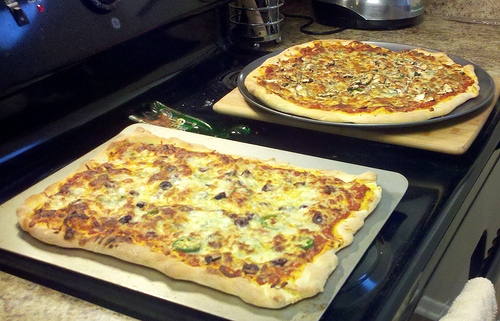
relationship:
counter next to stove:
[435, 19, 495, 59] [145, 41, 237, 125]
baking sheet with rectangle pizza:
[9, 134, 406, 318] [15, 129, 380, 311]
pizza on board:
[261, 30, 483, 125] [210, 77, 483, 164]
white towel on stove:
[453, 282, 496, 318] [343, 256, 395, 303]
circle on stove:
[33, 1, 42, 17] [207, 23, 498, 315]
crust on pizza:
[325, 103, 465, 126] [251, 23, 494, 126]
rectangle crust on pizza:
[13, 125, 378, 310] [14, 123, 381, 311]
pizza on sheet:
[47, 123, 367, 289] [25, 107, 421, 317]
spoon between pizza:
[149, 98, 249, 140] [14, 123, 381, 311]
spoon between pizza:
[149, 98, 249, 140] [243, 37, 480, 127]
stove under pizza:
[3, 5, 497, 316] [243, 37, 480, 127]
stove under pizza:
[3, 5, 497, 316] [14, 123, 381, 311]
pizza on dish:
[14, 123, 381, 311] [2, 123, 408, 318]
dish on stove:
[2, 123, 408, 318] [3, 5, 497, 316]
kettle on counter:
[353, 0, 421, 31] [429, 9, 494, 58]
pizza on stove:
[265, 17, 470, 134] [355, 127, 499, 304]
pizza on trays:
[265, 17, 470, 134] [16, 113, 383, 321]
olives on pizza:
[112, 199, 144, 224] [65, 139, 335, 291]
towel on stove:
[432, 275, 499, 318] [0, 45, 499, 317]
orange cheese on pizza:
[37, 129, 369, 284] [14, 123, 381, 311]